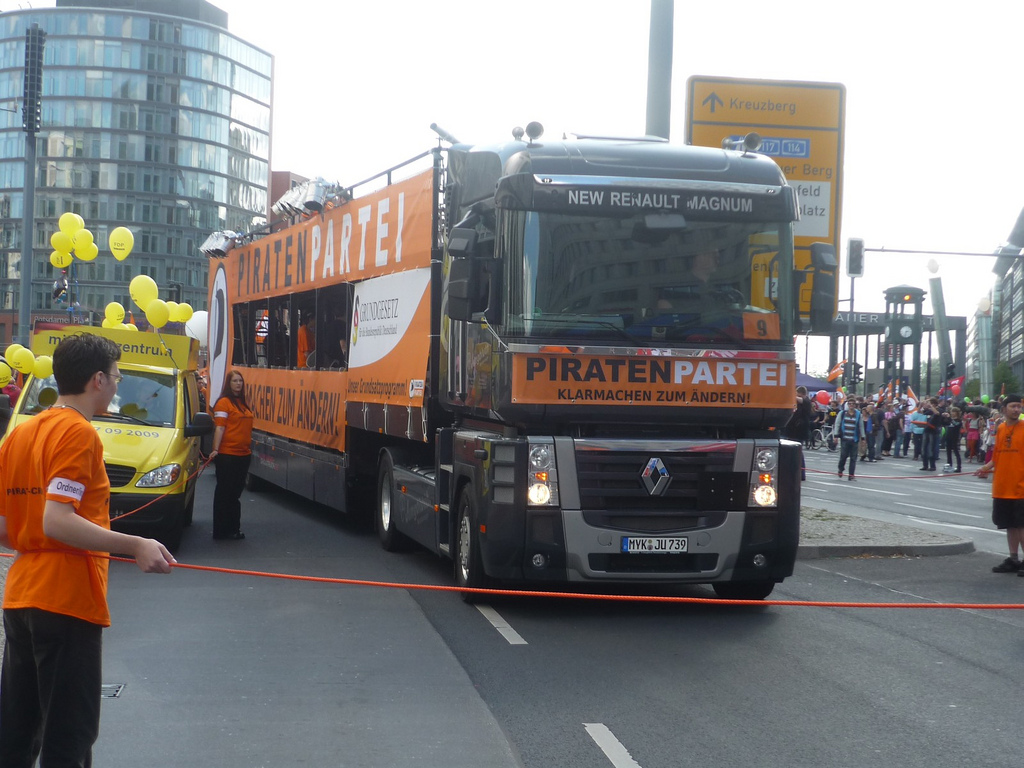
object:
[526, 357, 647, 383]
pirate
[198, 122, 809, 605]
bus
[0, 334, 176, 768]
man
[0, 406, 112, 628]
orange shirt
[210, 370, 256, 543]
woman standing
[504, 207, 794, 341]
window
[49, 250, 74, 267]
yellow balloons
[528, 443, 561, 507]
headlight